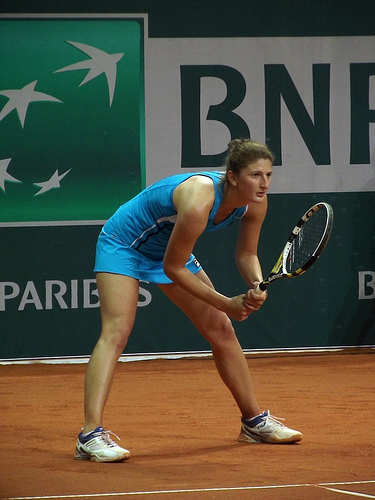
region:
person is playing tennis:
[68, 134, 334, 462]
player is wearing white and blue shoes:
[75, 411, 302, 459]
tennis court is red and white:
[0, 347, 373, 498]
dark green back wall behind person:
[1, 1, 373, 364]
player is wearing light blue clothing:
[94, 171, 249, 283]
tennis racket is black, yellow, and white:
[257, 198, 333, 290]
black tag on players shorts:
[193, 259, 201, 269]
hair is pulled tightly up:
[222, 138, 274, 192]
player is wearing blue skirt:
[88, 229, 200, 284]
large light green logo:
[1, 20, 145, 220]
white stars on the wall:
[0, 37, 125, 192]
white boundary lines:
[5, 481, 373, 499]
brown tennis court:
[1, 351, 373, 498]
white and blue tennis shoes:
[73, 412, 303, 459]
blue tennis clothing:
[93, 168, 247, 283]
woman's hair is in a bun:
[225, 140, 272, 175]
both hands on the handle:
[229, 279, 277, 320]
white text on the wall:
[0, 281, 153, 308]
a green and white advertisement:
[0, 13, 372, 344]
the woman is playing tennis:
[75, 140, 332, 462]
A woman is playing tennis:
[67, 128, 342, 468]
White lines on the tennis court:
[1, 472, 372, 495]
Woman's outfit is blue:
[90, 131, 273, 286]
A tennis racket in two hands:
[220, 197, 340, 322]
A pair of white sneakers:
[69, 407, 306, 467]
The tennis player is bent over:
[67, 128, 339, 465]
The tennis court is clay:
[0, 350, 370, 495]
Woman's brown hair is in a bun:
[216, 133, 277, 209]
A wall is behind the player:
[1, 1, 372, 359]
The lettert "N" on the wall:
[256, 55, 336, 168]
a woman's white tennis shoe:
[236, 414, 306, 445]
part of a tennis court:
[2, 353, 372, 499]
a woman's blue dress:
[92, 170, 245, 299]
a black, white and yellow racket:
[247, 200, 333, 301]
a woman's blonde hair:
[217, 135, 278, 176]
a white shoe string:
[103, 428, 123, 440]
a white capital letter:
[20, 279, 44, 310]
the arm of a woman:
[163, 186, 234, 314]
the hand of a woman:
[224, 293, 251, 322]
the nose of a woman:
[260, 172, 273, 190]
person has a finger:
[250, 289, 263, 298]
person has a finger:
[240, 303, 249, 312]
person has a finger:
[240, 308, 249, 314]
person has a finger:
[246, 291, 262, 306]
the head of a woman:
[219, 138, 268, 202]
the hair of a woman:
[232, 143, 267, 167]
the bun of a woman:
[227, 133, 247, 153]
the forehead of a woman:
[247, 157, 273, 172]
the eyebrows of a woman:
[251, 165, 273, 177]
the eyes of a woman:
[252, 173, 272, 178]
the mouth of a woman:
[253, 190, 266, 197]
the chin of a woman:
[250, 195, 270, 207]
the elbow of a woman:
[145, 262, 185, 284]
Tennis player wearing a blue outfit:
[85, 129, 280, 294]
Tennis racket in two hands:
[222, 190, 342, 325]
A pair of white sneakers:
[63, 401, 304, 463]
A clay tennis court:
[0, 345, 368, 495]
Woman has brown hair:
[215, 126, 277, 205]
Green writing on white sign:
[135, 30, 370, 197]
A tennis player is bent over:
[62, 126, 337, 465]